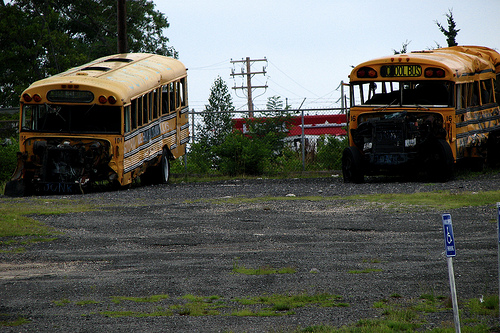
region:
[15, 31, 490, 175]
two broken down buses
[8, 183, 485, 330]
grass growing through the pavement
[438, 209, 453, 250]
blue and white sign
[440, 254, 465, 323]
pole sign is on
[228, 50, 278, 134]
utility pole in the distance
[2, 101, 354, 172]
fencing behind the buses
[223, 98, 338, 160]
red building behind the fencing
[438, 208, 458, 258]
blue and white handicapped sign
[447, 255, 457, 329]
sign post for a handicapped sign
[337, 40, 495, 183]
yellow school bus on the right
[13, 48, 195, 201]
yellow school bus on the left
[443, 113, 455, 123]
number 46 on a bus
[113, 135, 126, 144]
number 104 on a bus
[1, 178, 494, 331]
gravelly parking lot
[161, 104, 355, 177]
metal fence behind the buses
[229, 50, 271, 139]
tall wooden electrical post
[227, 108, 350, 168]
red building behind fence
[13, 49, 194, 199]
A bus missing both front tires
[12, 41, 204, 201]
broken down, dented bus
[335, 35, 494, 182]
school bus missing front end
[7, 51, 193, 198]
school bus missing its front end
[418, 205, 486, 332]
handicapped parking sign near buses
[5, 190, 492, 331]
gravelly field with patches of grass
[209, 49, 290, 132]
electrical pole with wires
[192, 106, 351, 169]
a chain link fence and bushes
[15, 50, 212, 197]
a school bus missing its windows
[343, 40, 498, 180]
a very dented and damaged school bus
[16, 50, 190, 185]
broken yellow school bus on the left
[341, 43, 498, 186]
broken yellow school bus on the right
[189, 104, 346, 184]
chain link fence between the two school buses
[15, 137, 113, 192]
engine of the school bus on the left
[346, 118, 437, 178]
engine of the school bus on the right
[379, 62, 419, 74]
School bus sign above the windshield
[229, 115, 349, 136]
red roof of a building behind the fence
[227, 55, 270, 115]
large telephone pole holding a lot of wires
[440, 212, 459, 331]
handicapped parking sign on silver pole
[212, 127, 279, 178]
bush in front of the fence between the buses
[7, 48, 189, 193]
Bus with smashed front end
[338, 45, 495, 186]
Crumpled school bus with smashed front end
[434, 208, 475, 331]
Handicapped parking sign attached to a pole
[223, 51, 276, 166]
Multi utility pole with wires attached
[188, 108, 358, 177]
A chain linked fence with metal posts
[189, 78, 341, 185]
Small trees and bushes behind a fence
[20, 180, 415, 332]
Asphalt with dirt and grass growing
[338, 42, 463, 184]
School bus number 16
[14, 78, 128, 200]
School bus number 104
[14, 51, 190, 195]
Only one tire visible on school bus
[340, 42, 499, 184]
Orange bus with front tires.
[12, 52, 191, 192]
Orange bus with no front wheels.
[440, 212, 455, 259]
White and blue handicapped sign.